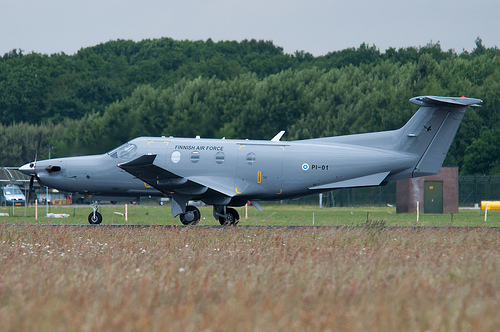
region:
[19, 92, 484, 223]
A Finnish Air Force airplane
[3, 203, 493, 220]
A grassy field near the airplane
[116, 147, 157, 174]
The wing of the plane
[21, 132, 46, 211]
A propellor at the front of the airplane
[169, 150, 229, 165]
Windows on the side of the airplane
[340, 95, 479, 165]
The tail of the airplane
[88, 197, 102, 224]
The wheel at the front of the plane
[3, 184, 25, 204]
A van near the grassy field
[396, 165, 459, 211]
A building on the grassy field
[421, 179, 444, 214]
A green door on the building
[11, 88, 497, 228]
gray plane parked on airstrip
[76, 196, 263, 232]
airplane landing gear down, resting on airstrip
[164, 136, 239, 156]
writing on plane identifies it as Finnish Air Force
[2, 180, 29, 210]
van in parking area near plane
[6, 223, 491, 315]
dry appearing brown vegetation in field near airstrip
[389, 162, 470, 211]
brick outdoor building with green door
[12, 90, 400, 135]
thickly forested area near air strip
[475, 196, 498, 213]
yellow cylinder or barrel laying horizontally on ground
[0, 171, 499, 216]
fence located on further side of aircraft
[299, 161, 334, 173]
identification numbers on aircraft PI-01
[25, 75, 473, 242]
the plane is grey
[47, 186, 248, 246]
the wheels are black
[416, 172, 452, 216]
the door is green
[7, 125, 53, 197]
the propeller is not moving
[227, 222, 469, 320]
the grass is brown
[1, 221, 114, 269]
white flowers in the grass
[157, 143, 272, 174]
windows on the side of the plane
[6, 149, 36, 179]
the nose of the plane is silver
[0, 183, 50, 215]
a car is parked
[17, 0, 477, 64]
the sky is overcast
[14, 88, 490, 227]
Airplane on runway of airport.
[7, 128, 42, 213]
Propeller on front of plane's nose.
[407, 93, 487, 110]
Horizontal stabilizer on top of plane's tail.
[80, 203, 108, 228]
Front landing wheel on plane.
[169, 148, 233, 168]
Windows on side of plane.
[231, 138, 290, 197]
Door on side of plane.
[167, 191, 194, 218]
Lowered flap underneath plane's wing.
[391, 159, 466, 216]
Out building on side of runway.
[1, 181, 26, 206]
Car parked on side of airplane hangar.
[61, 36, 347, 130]
Trees growing behind airplane hangar.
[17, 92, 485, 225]
long grey airplane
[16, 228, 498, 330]
dead grass in field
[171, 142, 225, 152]
finnish air force written on side of plane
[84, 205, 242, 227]
wheels set down on tarmac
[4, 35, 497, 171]
green leaves on trees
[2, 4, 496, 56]
clear cloudless blue sky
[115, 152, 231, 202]
black stripe on side of plane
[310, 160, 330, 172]
plane number P1-01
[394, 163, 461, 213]
brick power station in field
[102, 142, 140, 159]
window to cockpit